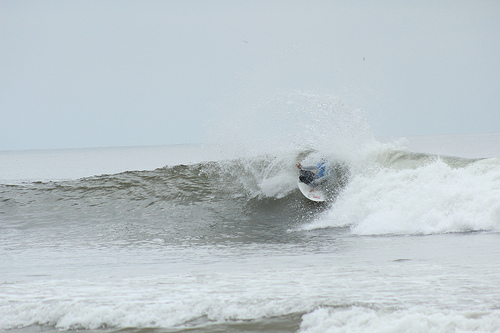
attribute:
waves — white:
[0, 150, 500, 236]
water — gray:
[10, 137, 498, 331]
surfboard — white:
[297, 179, 328, 202]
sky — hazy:
[1, 1, 499, 118]